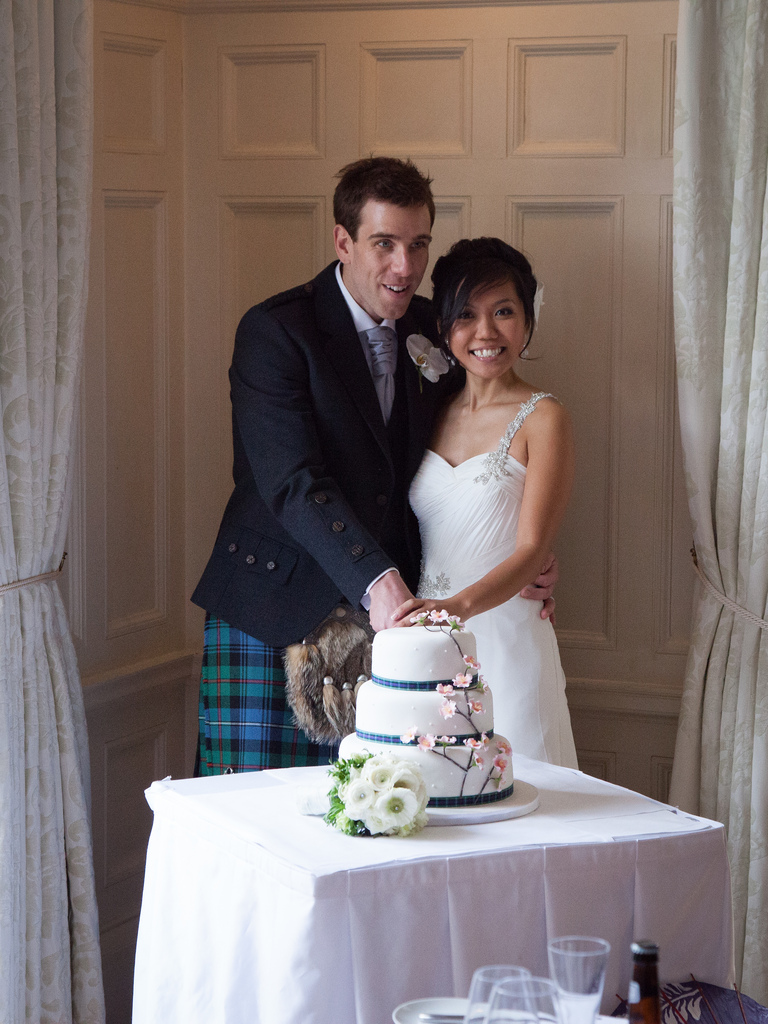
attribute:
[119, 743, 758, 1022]
cloth — view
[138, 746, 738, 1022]
table — view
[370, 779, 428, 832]
flower — view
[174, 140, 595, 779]
couple — cute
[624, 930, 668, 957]
opener — view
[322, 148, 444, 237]
hair — brown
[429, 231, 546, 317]
hair — black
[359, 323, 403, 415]
tie — gray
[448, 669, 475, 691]
flower — pink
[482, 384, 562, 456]
strap — gray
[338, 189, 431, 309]
head —  man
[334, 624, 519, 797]
cake — wedding , three-tiered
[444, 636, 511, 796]
flowers —  pink, small, climbing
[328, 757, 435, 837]
bouquet — bridal 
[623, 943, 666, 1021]
bottle — brown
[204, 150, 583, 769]
couple —  posing, behind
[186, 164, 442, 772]
groom — wearing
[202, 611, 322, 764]
kilt — plaid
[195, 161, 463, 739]
groom — arm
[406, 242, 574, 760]
bride's — waist